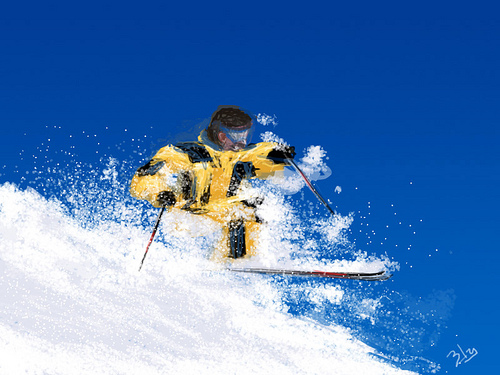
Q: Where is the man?
A: In the snow.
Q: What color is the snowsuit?
A: Yellow and black.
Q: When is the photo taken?
A: Daytime.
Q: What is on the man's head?
A: A visor.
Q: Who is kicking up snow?
A: The skier.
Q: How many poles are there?
A: Two.